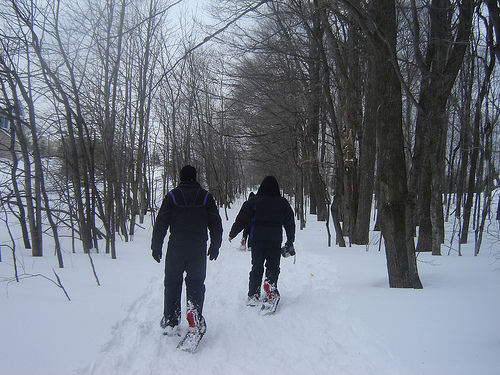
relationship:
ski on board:
[257, 292, 279, 317] [187, 309, 195, 329]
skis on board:
[168, 230, 362, 282] [117, 267, 247, 357]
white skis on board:
[152, 277, 293, 359] [259, 283, 282, 315]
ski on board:
[175, 312, 208, 354] [150, 279, 295, 367]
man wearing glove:
[151, 163, 223, 353] [203, 242, 222, 260]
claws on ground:
[293, 237, 330, 302] [31, 192, 498, 328]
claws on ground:
[170, 308, 210, 359] [11, 225, 498, 372]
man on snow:
[151, 163, 223, 353] [0, 151, 497, 373]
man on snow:
[234, 170, 302, 315] [0, 151, 497, 373]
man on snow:
[228, 173, 295, 318] [246, 317, 304, 361]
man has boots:
[147, 161, 224, 348] [157, 298, 206, 335]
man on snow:
[147, 161, 224, 348] [0, 151, 497, 373]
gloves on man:
[140, 244, 233, 269] [147, 158, 231, 350]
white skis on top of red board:
[152, 277, 293, 359] [146, 331, 227, 375]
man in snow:
[228, 173, 295, 318] [0, 290, 471, 375]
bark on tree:
[416, 171, 446, 256] [376, 171, 443, 329]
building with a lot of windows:
[72, 183, 156, 355] [2, 161, 496, 311]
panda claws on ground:
[192, 274, 306, 370] [1, 156, 496, 373]